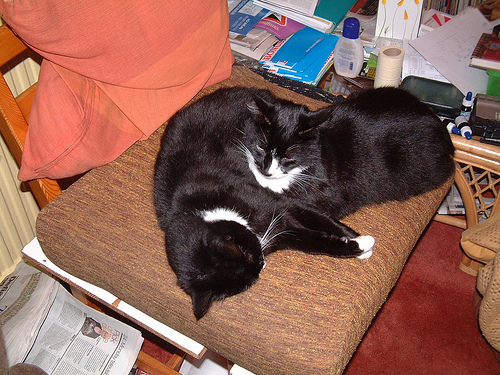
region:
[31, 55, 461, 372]
two black and white cats sharing a brown cushion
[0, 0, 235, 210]
orange pillow leaning against wood chair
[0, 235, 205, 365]
edge of white board above newspaper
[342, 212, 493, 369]
lacy beige fabric over red carpeting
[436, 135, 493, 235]
edge of wooden table with curve and diamond pattern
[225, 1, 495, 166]
clutter on top of table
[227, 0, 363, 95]
papers next to stack of envelopes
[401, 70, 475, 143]
black case next to little bottles with droppers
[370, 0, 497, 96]
large envelope between book and gift bag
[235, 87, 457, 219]
A black and white cat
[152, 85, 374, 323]
A black cat with white paws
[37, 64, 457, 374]
A brown seat cushion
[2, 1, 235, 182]
A pillow with a salmon colored case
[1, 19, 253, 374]
A wooden hard backed chair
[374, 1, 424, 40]
A greeting card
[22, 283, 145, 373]
A news paper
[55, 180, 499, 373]
A red carpet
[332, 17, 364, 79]
A blue and white bottle of lotion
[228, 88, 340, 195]
a black and white cat head.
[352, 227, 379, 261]
a couple of white paws.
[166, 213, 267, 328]
a cat with a black head.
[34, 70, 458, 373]
A cushion with cats.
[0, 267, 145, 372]
a news paper on the ground.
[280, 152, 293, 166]
a cat's left eye.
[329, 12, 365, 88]
a bottle on a table.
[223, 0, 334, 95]
a book on a table.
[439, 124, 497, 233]
a brown piece of furniture.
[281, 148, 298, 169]
A left cat eye.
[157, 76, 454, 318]
Two black and white cats.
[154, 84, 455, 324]
Two cats snuggled together.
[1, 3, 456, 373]
Cats laying on a chair.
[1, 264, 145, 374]
A newspaper.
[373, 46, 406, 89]
A roll of toilet paper.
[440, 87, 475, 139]
Three dropper bottles.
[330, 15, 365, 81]
A bottle with a blue cap.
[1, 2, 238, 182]
An orange pillow.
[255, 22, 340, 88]
Some photograph envelopes.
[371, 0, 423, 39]
A greeting card with yellow flowers on it.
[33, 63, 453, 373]
Two cats lying on a pillow.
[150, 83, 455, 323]
Two black and white cats sleeping.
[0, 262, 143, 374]
A newspaper on the ground.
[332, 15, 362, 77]
A small white bottle with a blue cap.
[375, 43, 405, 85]
A roll of toilet paper.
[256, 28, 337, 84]
A stack of blue papers.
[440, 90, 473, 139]
Three small medicine bottles.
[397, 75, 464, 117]
A black case for glasses.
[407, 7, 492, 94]
A white piece of paper with writing on it.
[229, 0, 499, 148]
Items scattered on a small table.